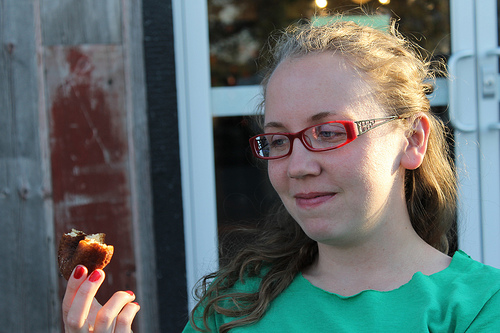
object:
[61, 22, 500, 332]
girl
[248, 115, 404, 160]
glasses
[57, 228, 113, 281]
donut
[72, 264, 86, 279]
fingernail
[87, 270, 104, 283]
fingernail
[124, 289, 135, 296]
fingernail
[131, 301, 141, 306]
fingernail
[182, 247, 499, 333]
shirt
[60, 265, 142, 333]
hand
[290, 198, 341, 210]
lips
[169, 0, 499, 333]
door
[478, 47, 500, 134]
handle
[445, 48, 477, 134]
handle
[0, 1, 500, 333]
building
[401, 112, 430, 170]
ear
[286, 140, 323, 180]
nose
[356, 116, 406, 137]
side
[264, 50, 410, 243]
face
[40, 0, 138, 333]
paint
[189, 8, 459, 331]
hair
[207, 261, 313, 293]
shoulder